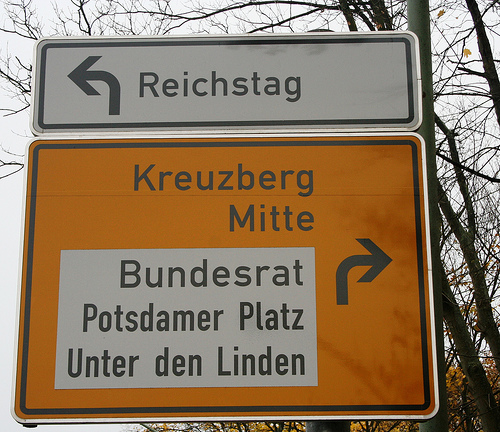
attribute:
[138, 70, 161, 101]
letter — color black, written, black, dark, painted black, written in black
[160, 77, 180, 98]
letter — written, black, color black, dark, painted black, written in black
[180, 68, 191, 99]
letter — written, black, dark, painted black, written in black, color black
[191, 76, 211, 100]
letter — written, black, dark, painted black, written in black, color black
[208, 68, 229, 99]
letter — written, black, dark, painted black, written in black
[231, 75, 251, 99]
letter — color black, written, black, written in black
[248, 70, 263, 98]
letter — written, black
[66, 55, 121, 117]
arrow — black, pointing left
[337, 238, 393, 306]
arrow — black, pointing right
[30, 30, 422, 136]
sign — white, german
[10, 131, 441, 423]
sign — yellow, yellow white black, german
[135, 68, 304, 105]
writing — black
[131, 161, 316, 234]
writing — black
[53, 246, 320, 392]
box — white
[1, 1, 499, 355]
sky — gray, overhead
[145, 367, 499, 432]
trees — yellow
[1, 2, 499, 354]
trees — leafless